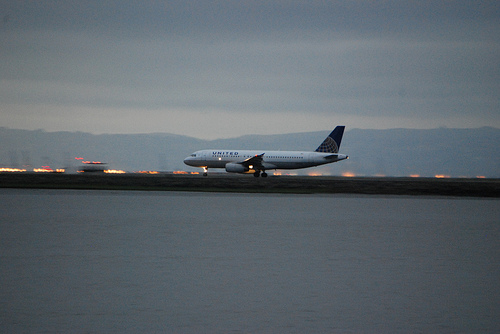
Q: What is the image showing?
A: It is showing a lake.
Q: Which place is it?
A: It is a lake.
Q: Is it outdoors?
A: Yes, it is outdoors.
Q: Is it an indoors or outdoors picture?
A: It is outdoors.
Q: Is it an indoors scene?
A: No, it is outdoors.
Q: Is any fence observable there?
A: No, there are no fences.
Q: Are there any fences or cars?
A: No, there are no fences or cars.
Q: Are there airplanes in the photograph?
A: Yes, there is an airplane.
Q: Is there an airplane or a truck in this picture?
A: Yes, there is an airplane.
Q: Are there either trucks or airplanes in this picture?
A: Yes, there is an airplane.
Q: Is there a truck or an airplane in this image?
A: Yes, there is an airplane.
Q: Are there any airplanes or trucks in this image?
A: Yes, there is an airplane.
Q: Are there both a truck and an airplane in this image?
A: No, there is an airplane but no trucks.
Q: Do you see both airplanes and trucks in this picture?
A: No, there is an airplane but no trucks.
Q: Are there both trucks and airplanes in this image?
A: No, there is an airplane but no trucks.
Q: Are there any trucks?
A: No, there are no trucks.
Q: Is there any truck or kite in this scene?
A: No, there are no trucks or kites.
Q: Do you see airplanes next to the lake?
A: Yes, there is an airplane next to the lake.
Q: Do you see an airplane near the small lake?
A: Yes, there is an airplane near the lake.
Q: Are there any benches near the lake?
A: No, there is an airplane near the lake.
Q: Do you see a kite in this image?
A: No, there are no kites.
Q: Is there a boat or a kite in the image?
A: No, there are no kites or boats.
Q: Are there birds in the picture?
A: No, there are no birds.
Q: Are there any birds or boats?
A: No, there are no birds or boats.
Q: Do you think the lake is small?
A: Yes, the lake is small.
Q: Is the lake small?
A: Yes, the lake is small.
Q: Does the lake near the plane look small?
A: Yes, the lake is small.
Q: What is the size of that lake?
A: The lake is small.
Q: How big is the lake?
A: The lake is small.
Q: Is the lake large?
A: No, the lake is small.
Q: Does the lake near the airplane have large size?
A: No, the lake is small.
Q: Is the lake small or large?
A: The lake is small.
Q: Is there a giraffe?
A: No, there are no giraffes.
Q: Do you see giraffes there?
A: No, there are no giraffes.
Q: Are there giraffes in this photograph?
A: No, there are no giraffes.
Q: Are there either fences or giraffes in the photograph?
A: No, there are no giraffes or fences.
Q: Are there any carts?
A: No, there are no carts.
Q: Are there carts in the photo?
A: No, there are no carts.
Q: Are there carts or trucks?
A: No, there are no carts or trucks.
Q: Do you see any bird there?
A: No, there are no birds.